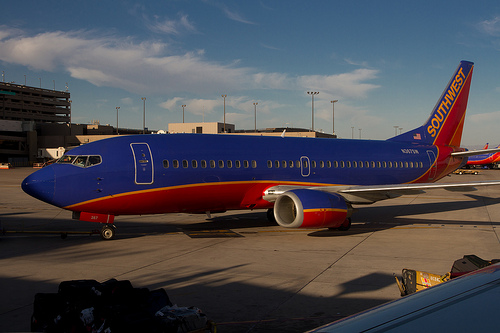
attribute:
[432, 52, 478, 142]
tail — airline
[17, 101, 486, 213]
plane — parked, blue, southwest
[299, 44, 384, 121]
clouds — white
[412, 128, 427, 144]
flag — painted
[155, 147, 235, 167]
window — part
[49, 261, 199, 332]
luggage — stacks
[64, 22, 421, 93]
sky — up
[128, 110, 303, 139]
building — airpot